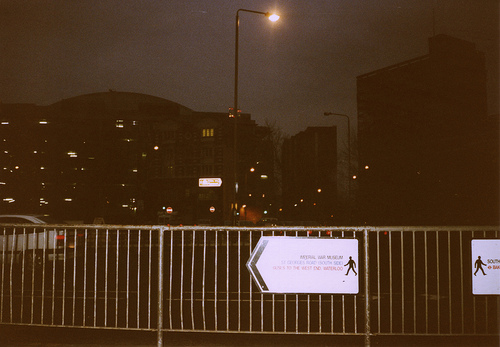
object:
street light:
[267, 12, 280, 23]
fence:
[0, 224, 500, 346]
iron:
[29, 227, 37, 324]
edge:
[311, 291, 325, 296]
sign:
[198, 177, 224, 188]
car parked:
[0, 211, 86, 273]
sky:
[0, 0, 500, 197]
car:
[0, 209, 86, 274]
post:
[230, 6, 270, 227]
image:
[343, 255, 358, 276]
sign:
[467, 235, 500, 298]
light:
[57, 235, 64, 239]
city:
[0, 0, 499, 347]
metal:
[149, 225, 234, 331]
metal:
[156, 224, 167, 328]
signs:
[165, 206, 173, 214]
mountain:
[49, 87, 194, 113]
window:
[201, 127, 215, 138]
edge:
[282, 225, 314, 239]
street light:
[322, 111, 331, 116]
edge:
[259, 284, 296, 296]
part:
[156, 271, 174, 296]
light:
[38, 120, 48, 124]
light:
[153, 145, 159, 151]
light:
[249, 167, 256, 173]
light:
[293, 203, 297, 207]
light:
[364, 165, 370, 170]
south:
[490, 260, 499, 267]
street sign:
[209, 205, 216, 213]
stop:
[166, 206, 173, 213]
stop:
[209, 206, 215, 213]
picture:
[0, 0, 500, 346]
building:
[0, 87, 278, 226]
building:
[279, 124, 338, 227]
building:
[355, 28, 500, 228]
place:
[2, 79, 275, 228]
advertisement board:
[244, 234, 362, 295]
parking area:
[0, 212, 396, 290]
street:
[0, 209, 500, 347]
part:
[297, 280, 309, 284]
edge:
[283, 292, 291, 294]